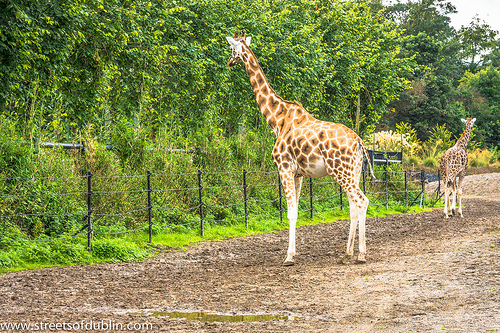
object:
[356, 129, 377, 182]
tail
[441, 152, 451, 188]
tail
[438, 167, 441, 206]
post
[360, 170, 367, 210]
post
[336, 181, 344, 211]
post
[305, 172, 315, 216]
post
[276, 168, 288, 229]
post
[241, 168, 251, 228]
post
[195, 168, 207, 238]
post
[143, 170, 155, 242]
post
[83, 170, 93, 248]
post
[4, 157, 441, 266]
wire fence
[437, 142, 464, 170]
ground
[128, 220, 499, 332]
road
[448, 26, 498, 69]
sky patch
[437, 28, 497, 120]
trees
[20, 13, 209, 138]
woods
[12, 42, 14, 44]
foliage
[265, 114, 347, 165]
spots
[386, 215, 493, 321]
dirt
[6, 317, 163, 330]
website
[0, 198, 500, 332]
dirt trail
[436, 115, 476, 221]
animal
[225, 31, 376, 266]
animal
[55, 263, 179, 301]
part ground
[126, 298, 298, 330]
puddle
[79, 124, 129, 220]
bushes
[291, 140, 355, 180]
spots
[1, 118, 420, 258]
vegetation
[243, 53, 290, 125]
neck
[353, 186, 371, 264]
leg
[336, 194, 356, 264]
leg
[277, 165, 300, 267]
leg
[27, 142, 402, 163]
pipe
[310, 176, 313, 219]
black wooden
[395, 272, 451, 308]
ground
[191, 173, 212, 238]
post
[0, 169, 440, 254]
fence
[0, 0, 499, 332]
area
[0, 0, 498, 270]
woods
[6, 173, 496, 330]
trail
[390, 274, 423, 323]
part